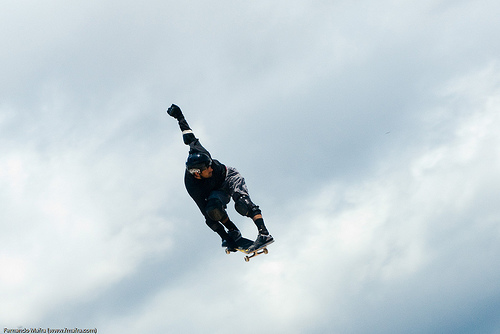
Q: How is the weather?
A: It is cloudy.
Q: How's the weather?
A: It is cloudy.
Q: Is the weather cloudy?
A: Yes, it is cloudy.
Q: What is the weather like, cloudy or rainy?
A: It is cloudy.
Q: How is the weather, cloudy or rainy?
A: It is cloudy.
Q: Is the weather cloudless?
A: No, it is cloudy.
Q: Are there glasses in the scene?
A: No, there are no glasses.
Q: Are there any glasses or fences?
A: No, there are no glasses or fences.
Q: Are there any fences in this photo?
A: No, there are no fences.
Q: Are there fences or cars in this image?
A: No, there are no fences or cars.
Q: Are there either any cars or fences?
A: No, there are no fences or cars.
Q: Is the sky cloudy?
A: Yes, the sky is cloudy.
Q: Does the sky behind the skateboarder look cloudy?
A: Yes, the sky is cloudy.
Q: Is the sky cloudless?
A: No, the sky is cloudy.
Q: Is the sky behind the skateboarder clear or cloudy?
A: The sky is cloudy.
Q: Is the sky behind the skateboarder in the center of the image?
A: Yes, the sky is behind the skateboarder.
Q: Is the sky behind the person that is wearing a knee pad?
A: Yes, the sky is behind the skateboarder.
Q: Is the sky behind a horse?
A: No, the sky is behind the skateboarder.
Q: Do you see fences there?
A: No, there are no fences.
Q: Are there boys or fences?
A: No, there are no fences or boys.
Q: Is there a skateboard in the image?
A: Yes, there is a skateboard.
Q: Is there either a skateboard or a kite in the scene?
A: Yes, there is a skateboard.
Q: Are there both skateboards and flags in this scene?
A: No, there is a skateboard but no flags.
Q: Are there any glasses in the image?
A: No, there are no glasses.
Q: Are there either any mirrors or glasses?
A: No, there are no glasses or mirrors.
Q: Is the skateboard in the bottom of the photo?
A: Yes, the skateboard is in the bottom of the image.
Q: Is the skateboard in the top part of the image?
A: No, the skateboard is in the bottom of the image.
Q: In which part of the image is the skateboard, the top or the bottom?
A: The skateboard is in the bottom of the image.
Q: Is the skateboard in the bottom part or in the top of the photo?
A: The skateboard is in the bottom of the image.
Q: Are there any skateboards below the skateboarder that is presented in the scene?
A: Yes, there is a skateboard below the skateboarder.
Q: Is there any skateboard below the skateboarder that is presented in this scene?
A: Yes, there is a skateboard below the skateboarder.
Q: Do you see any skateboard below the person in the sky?
A: Yes, there is a skateboard below the skateboarder.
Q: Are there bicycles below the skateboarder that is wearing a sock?
A: No, there is a skateboard below the skateboarder.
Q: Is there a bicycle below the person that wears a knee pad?
A: No, there is a skateboard below the skateboarder.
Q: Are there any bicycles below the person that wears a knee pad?
A: No, there is a skateboard below the skateboarder.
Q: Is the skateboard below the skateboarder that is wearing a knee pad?
A: Yes, the skateboard is below the skateboarder.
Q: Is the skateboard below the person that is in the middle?
A: Yes, the skateboard is below the skateboarder.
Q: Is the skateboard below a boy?
A: No, the skateboard is below the skateboarder.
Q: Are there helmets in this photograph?
A: Yes, there is a helmet.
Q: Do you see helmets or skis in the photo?
A: Yes, there is a helmet.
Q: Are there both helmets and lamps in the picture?
A: No, there is a helmet but no lamps.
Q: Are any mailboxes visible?
A: No, there are no mailboxes.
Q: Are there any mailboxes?
A: No, there are no mailboxes.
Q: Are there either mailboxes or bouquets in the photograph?
A: No, there are no mailboxes or bouquets.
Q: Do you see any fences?
A: No, there are no fences.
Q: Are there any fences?
A: No, there are no fences.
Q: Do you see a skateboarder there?
A: Yes, there is a skateboarder.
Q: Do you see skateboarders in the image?
A: Yes, there is a skateboarder.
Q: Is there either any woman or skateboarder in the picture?
A: Yes, there is a skateboarder.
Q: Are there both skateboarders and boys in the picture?
A: No, there is a skateboarder but no boys.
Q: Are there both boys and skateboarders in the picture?
A: No, there is a skateboarder but no boys.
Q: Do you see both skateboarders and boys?
A: No, there is a skateboarder but no boys.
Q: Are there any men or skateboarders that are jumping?
A: Yes, the skateboarder is jumping.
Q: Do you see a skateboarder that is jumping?
A: Yes, there is a skateboarder that is jumping.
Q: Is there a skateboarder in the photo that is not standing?
A: Yes, there is a skateboarder that is jumping.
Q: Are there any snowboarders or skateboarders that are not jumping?
A: No, there is a skateboarder but he is jumping.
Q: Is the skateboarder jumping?
A: Yes, the skateboarder is jumping.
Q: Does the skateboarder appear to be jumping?
A: Yes, the skateboarder is jumping.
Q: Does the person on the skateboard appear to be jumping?
A: Yes, the skateboarder is jumping.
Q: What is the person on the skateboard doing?
A: The skateboarder is jumping.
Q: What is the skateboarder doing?
A: The skateboarder is jumping.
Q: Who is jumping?
A: The skateboarder is jumping.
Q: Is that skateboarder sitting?
A: No, the skateboarder is jumping.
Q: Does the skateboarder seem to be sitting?
A: No, the skateboarder is jumping.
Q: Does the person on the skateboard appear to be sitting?
A: No, the skateboarder is jumping.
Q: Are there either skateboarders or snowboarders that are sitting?
A: No, there is a skateboarder but he is jumping.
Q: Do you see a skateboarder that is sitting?
A: No, there is a skateboarder but he is jumping.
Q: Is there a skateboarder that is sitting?
A: No, there is a skateboarder but he is jumping.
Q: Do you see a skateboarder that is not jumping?
A: No, there is a skateboarder but he is jumping.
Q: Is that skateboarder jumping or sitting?
A: The skateboarder is jumping.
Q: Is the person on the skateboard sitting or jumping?
A: The skateboarder is jumping.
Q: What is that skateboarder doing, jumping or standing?
A: The skateboarder is jumping.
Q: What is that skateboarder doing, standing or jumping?
A: The skateboarder is jumping.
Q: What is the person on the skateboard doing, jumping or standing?
A: The skateboarder is jumping.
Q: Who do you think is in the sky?
A: The skateboarder is in the sky.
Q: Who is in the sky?
A: The skateboarder is in the sky.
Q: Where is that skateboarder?
A: The skateboarder is in the sky.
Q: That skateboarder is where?
A: The skateboarder is in the sky.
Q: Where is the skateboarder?
A: The skateboarder is in the sky.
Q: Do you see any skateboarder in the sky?
A: Yes, there is a skateboarder in the sky.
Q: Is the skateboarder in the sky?
A: Yes, the skateboarder is in the sky.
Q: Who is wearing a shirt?
A: The skateboarder is wearing a shirt.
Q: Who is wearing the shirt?
A: The skateboarder is wearing a shirt.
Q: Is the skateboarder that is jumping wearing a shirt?
A: Yes, the skateboarder is wearing a shirt.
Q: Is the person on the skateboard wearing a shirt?
A: Yes, the skateboarder is wearing a shirt.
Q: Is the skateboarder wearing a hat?
A: No, the skateboarder is wearing a shirt.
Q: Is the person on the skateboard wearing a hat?
A: No, the skateboarder is wearing a shirt.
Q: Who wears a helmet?
A: The skateboarder wears a helmet.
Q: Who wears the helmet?
A: The skateboarder wears a helmet.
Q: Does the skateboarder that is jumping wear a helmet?
A: Yes, the skateboarder wears a helmet.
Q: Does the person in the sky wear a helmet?
A: Yes, the skateboarder wears a helmet.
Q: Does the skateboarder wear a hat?
A: No, the skateboarder wears a helmet.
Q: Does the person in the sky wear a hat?
A: No, the skateboarder wears a helmet.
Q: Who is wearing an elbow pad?
A: The skateboarder is wearing an elbow pad.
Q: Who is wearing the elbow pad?
A: The skateboarder is wearing an elbow pad.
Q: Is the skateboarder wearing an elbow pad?
A: Yes, the skateboarder is wearing an elbow pad.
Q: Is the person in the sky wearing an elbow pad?
A: Yes, the skateboarder is wearing an elbow pad.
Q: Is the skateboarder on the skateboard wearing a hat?
A: No, the skateboarder is wearing an elbow pad.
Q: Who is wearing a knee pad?
A: The skateboarder is wearing a knee pad.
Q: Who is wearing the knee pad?
A: The skateboarder is wearing a knee pad.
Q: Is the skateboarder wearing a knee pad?
A: Yes, the skateboarder is wearing a knee pad.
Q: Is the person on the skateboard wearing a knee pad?
A: Yes, the skateboarder is wearing a knee pad.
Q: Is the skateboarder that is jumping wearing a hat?
A: No, the skateboarder is wearing a knee pad.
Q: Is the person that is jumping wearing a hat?
A: No, the skateboarder is wearing a knee pad.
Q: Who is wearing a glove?
A: The skateboarder is wearing a glove.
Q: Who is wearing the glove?
A: The skateboarder is wearing a glove.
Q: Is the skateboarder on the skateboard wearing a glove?
A: Yes, the skateboarder is wearing a glove.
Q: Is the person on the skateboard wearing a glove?
A: Yes, the skateboarder is wearing a glove.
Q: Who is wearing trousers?
A: The skateboarder is wearing trousers.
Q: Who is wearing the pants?
A: The skateboarder is wearing trousers.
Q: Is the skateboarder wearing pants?
A: Yes, the skateboarder is wearing pants.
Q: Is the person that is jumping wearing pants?
A: Yes, the skateboarder is wearing pants.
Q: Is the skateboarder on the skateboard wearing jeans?
A: No, the skateboarder is wearing pants.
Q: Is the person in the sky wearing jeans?
A: No, the skateboarder is wearing pants.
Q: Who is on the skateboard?
A: The skateboarder is on the skateboard.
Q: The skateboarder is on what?
A: The skateboarder is on the skateboard.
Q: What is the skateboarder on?
A: The skateboarder is on the skateboard.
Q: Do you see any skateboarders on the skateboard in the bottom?
A: Yes, there is a skateboarder on the skateboard.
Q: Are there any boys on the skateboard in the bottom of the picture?
A: No, there is a skateboarder on the skateboard.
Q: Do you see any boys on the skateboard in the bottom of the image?
A: No, there is a skateboarder on the skateboard.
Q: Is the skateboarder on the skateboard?
A: Yes, the skateboarder is on the skateboard.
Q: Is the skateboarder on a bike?
A: No, the skateboarder is on the skateboard.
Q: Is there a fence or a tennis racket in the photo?
A: No, there are no fences or rackets.